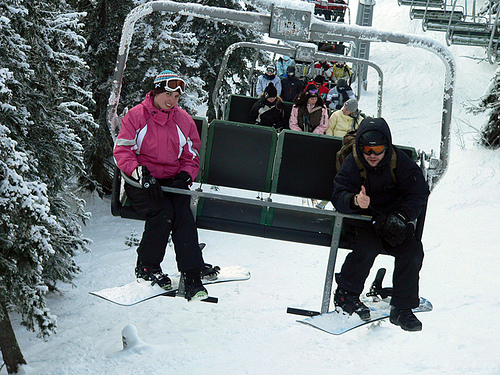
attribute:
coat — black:
[326, 159, 474, 262]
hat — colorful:
[150, 67, 180, 84]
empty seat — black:
[196, 120, 272, 230]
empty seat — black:
[275, 127, 345, 247]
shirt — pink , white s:
[112, 94, 206, 179]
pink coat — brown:
[290, 100, 330, 139]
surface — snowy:
[170, 308, 270, 373]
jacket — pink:
[113, 102, 200, 186]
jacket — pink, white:
[116, 102, 201, 197]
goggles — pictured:
[352, 144, 414, 160]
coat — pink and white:
[112, 92, 205, 188]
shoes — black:
[324, 285, 427, 334]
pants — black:
[127, 176, 207, 275]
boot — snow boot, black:
[389, 307, 424, 332]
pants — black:
[335, 216, 425, 309]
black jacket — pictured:
[345, 162, 359, 178]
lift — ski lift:
[75, 0, 489, 345]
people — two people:
[119, 39, 429, 340]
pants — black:
[292, 198, 443, 293]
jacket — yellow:
[322, 110, 347, 137]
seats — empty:
[135, 93, 450, 275]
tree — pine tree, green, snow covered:
[0, 0, 100, 373]